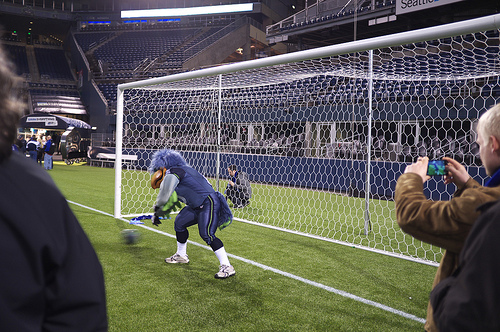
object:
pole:
[113, 82, 126, 219]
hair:
[478, 100, 498, 146]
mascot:
[146, 147, 238, 279]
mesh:
[254, 100, 382, 183]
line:
[127, 212, 426, 326]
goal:
[115, 0, 498, 330]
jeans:
[44, 151, 53, 170]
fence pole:
[113, 90, 124, 217]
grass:
[82, 200, 423, 330]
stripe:
[244, 259, 416, 330]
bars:
[112, 65, 413, 244]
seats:
[23, 117, 108, 165]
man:
[392, 103, 500, 332]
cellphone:
[427, 159, 446, 176]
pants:
[173, 192, 233, 252]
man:
[43, 134, 56, 170]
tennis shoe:
[213, 264, 238, 279]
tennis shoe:
[164, 251, 191, 265]